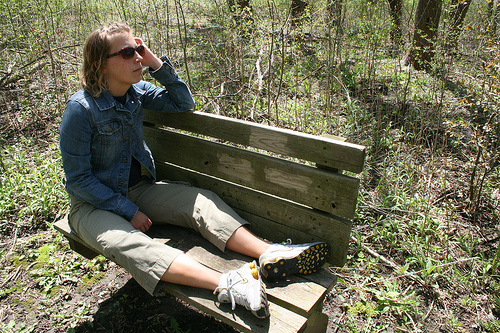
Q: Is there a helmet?
A: No, there are no helmets.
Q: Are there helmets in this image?
A: No, there are no helmets.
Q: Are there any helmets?
A: No, there are no helmets.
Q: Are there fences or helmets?
A: No, there are no helmets or fences.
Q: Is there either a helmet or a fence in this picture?
A: No, there are no helmets or fences.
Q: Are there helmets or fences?
A: No, there are no helmets or fences.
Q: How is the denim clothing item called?
A: The clothing item is a jacket.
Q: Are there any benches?
A: Yes, there is a bench.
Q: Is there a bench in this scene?
A: Yes, there is a bench.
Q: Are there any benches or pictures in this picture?
A: Yes, there is a bench.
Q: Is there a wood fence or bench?
A: Yes, there is a wood bench.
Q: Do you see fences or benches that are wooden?
A: Yes, the bench is wooden.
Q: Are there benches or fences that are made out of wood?
A: Yes, the bench is made of wood.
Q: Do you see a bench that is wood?
A: Yes, there is a wood bench.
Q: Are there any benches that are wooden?
A: Yes, there is a bench that is wooden.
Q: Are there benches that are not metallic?
A: Yes, there is a wooden bench.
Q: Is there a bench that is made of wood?
A: Yes, there is a bench that is made of wood.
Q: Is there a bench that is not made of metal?
A: Yes, there is a bench that is made of wood.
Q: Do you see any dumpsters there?
A: No, there are no dumpsters.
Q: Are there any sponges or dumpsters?
A: No, there are no dumpsters or sponges.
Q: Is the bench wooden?
A: Yes, the bench is wooden.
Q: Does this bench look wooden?
A: Yes, the bench is wooden.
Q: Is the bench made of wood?
A: Yes, the bench is made of wood.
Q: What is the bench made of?
A: The bench is made of wood.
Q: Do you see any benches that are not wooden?
A: No, there is a bench but it is wooden.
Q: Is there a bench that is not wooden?
A: No, there is a bench but it is wooden.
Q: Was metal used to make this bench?
A: No, the bench is made of wood.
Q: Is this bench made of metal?
A: No, the bench is made of wood.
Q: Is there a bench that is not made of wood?
A: No, there is a bench but it is made of wood.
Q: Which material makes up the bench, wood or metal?
A: The bench is made of wood.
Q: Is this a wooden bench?
A: Yes, this is a wooden bench.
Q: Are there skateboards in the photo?
A: No, there are no skateboards.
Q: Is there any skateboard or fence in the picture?
A: No, there are no skateboards or fences.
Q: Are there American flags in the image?
A: No, there are no American flags.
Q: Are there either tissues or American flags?
A: No, there are no American flags or tissues.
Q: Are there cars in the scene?
A: No, there are no cars.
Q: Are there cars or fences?
A: No, there are no cars or fences.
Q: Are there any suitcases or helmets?
A: No, there are no helmets or suitcases.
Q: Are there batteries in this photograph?
A: No, there are no batteries.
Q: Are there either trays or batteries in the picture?
A: No, there are no batteries or trays.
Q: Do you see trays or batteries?
A: No, there are no batteries or trays.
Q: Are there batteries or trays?
A: No, there are no batteries or trays.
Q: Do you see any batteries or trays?
A: No, there are no batteries or trays.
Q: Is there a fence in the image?
A: No, there are no fences.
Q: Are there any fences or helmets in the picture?
A: No, there are no fences or helmets.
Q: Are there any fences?
A: No, there are no fences.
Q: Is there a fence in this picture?
A: No, there are no fences.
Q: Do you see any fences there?
A: No, there are no fences.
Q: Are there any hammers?
A: No, there are no hammers.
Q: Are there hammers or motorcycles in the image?
A: No, there are no hammers or motorcycles.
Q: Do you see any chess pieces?
A: No, there are no chess pieces.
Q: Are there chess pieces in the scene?
A: No, there are no chess pieces.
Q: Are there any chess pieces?
A: No, there are no chess pieces.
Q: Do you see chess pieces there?
A: No, there are no chess pieces.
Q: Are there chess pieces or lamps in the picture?
A: No, there are no chess pieces or lamps.